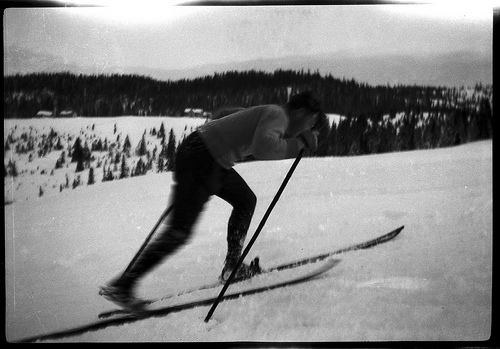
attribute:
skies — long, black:
[97, 225, 402, 318]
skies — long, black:
[8, 257, 336, 340]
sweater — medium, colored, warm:
[201, 105, 266, 159]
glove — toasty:
[307, 122, 333, 154]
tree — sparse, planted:
[36, 181, 46, 198]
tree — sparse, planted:
[85, 161, 100, 186]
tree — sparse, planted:
[134, 130, 151, 157]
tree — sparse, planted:
[84, 160, 96, 185]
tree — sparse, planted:
[8, 159, 20, 176]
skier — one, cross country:
[98, 88, 324, 313]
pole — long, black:
[204, 137, 316, 322]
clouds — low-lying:
[0, 3, 490, 89]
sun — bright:
[58, 0, 199, 31]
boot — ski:
[92, 246, 184, 313]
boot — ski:
[219, 235, 260, 286]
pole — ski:
[198, 131, 329, 341]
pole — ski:
[101, 177, 179, 304]